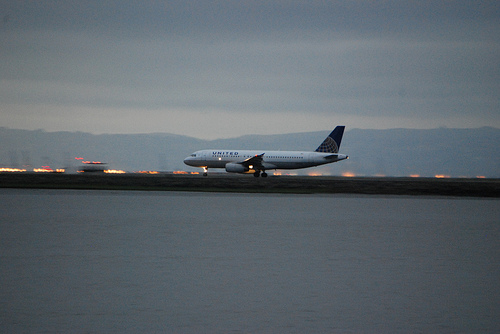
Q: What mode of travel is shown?
A: Airplane.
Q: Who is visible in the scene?
A: No one.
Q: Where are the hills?
A: In the background.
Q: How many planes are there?
A: One.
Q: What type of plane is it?
A: Passenger.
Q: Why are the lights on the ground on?
A: They are on a landing strip.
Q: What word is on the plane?
A: UNITED.